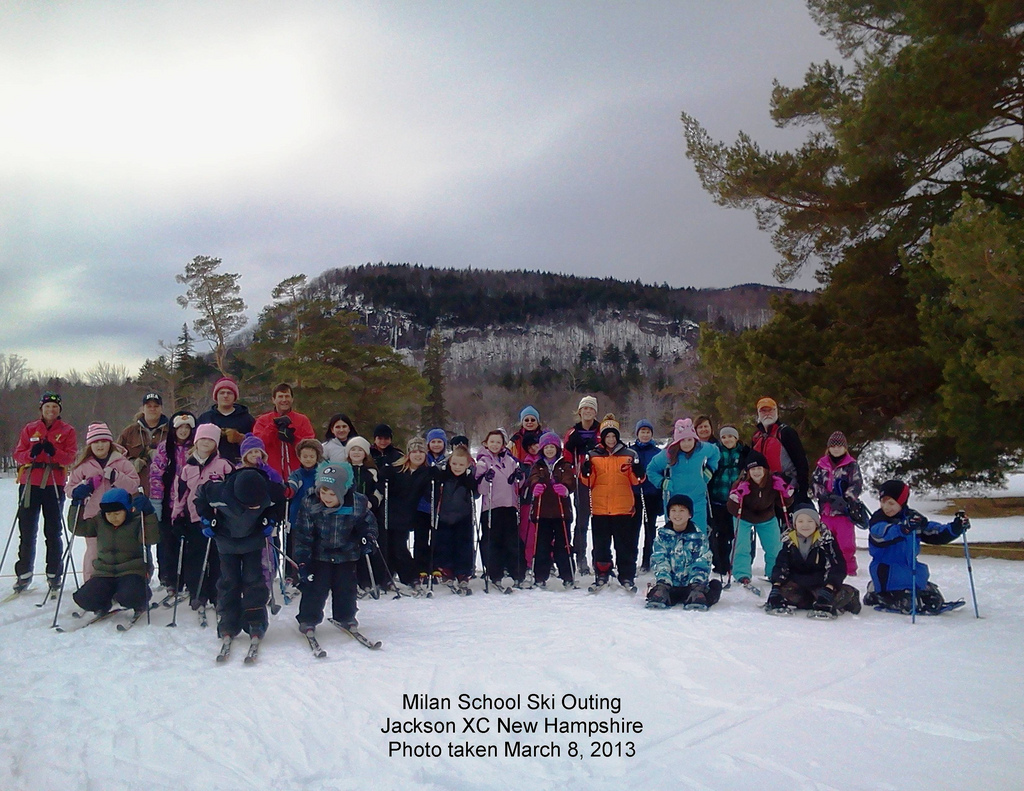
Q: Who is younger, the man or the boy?
A: The boy is younger than the man.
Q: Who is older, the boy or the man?
A: The man is older than the boy.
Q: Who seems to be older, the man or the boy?
A: The man is older than the boy.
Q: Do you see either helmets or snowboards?
A: No, there are no helmets or snowboards.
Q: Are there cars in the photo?
A: No, there are no cars.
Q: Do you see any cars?
A: No, there are no cars.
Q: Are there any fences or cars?
A: No, there are no cars or fences.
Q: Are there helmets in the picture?
A: No, there are no helmets.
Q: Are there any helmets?
A: No, there are no helmets.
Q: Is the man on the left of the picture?
A: Yes, the man is on the left of the image.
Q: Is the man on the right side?
A: No, the man is on the left of the image.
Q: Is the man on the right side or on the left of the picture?
A: The man is on the left of the image.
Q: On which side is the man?
A: The man is on the left of the image.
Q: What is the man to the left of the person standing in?
A: The man is standing in the snow.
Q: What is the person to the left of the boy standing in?
A: The man is standing in the snow.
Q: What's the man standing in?
A: The man is standing in the snow.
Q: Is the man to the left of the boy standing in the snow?
A: Yes, the man is standing in the snow.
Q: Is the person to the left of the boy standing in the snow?
A: Yes, the man is standing in the snow.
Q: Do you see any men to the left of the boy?
A: Yes, there is a man to the left of the boy.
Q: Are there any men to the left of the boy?
A: Yes, there is a man to the left of the boy.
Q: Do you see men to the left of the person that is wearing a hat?
A: Yes, there is a man to the left of the boy.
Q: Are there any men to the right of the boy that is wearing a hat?
A: No, the man is to the left of the boy.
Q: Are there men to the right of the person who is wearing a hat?
A: No, the man is to the left of the boy.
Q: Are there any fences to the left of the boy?
A: No, there is a man to the left of the boy.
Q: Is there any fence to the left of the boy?
A: No, there is a man to the left of the boy.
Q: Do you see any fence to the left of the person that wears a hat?
A: No, there is a man to the left of the boy.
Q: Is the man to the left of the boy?
A: Yes, the man is to the left of the boy.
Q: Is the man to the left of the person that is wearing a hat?
A: Yes, the man is to the left of the boy.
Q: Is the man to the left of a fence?
A: No, the man is to the left of the boy.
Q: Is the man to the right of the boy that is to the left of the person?
A: No, the man is to the left of the boy.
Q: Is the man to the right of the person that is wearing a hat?
A: No, the man is to the left of the boy.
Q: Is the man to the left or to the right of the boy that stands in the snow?
A: The man is to the left of the boy.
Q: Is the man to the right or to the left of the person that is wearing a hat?
A: The man is to the left of the boy.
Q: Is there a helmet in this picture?
A: No, there are no helmets.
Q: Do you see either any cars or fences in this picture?
A: No, there are no fences or cars.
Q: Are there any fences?
A: No, there are no fences.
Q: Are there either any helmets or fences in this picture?
A: No, there are no fences or helmets.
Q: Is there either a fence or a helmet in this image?
A: No, there are no fences or helmets.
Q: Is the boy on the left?
A: Yes, the boy is on the left of the image.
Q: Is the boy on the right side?
A: No, the boy is on the left of the image.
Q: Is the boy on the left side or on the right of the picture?
A: The boy is on the left of the image.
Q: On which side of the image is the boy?
A: The boy is on the left of the image.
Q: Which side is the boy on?
A: The boy is on the left of the image.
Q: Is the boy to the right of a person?
A: No, the boy is to the left of a person.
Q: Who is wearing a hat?
A: The boy is wearing a hat.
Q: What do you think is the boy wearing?
A: The boy is wearing a hat.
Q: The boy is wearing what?
A: The boy is wearing a hat.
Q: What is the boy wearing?
A: The boy is wearing a hat.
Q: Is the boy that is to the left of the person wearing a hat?
A: Yes, the boy is wearing a hat.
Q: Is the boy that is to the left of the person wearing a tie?
A: No, the boy is wearing a hat.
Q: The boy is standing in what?
A: The boy is standing in the snow.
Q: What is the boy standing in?
A: The boy is standing in the snow.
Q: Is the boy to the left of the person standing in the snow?
A: Yes, the boy is standing in the snow.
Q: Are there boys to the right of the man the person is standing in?
A: Yes, there is a boy to the right of the man.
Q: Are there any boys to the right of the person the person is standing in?
A: Yes, there is a boy to the right of the man.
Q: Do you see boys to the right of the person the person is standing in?
A: Yes, there is a boy to the right of the man.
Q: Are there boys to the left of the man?
A: No, the boy is to the right of the man.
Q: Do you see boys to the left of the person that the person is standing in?
A: No, the boy is to the right of the man.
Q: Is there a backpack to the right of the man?
A: No, there is a boy to the right of the man.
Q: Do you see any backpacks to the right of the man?
A: No, there is a boy to the right of the man.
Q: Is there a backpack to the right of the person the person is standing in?
A: No, there is a boy to the right of the man.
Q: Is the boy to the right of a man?
A: Yes, the boy is to the right of a man.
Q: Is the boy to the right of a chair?
A: No, the boy is to the right of a man.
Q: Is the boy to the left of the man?
A: No, the boy is to the right of the man.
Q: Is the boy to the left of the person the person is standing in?
A: No, the boy is to the right of the man.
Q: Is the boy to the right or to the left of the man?
A: The boy is to the right of the man.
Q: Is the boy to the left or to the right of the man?
A: The boy is to the right of the man.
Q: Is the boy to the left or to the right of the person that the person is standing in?
A: The boy is to the right of the man.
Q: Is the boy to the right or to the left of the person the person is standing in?
A: The boy is to the right of the man.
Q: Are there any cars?
A: No, there are no cars.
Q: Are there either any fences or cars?
A: No, there are no cars or fences.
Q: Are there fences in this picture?
A: No, there are no fences.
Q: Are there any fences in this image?
A: No, there are no fences.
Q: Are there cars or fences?
A: No, there are no fences or cars.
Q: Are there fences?
A: No, there are no fences.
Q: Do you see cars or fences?
A: No, there are no fences or cars.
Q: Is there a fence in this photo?
A: No, there are no fences.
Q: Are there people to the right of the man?
A: Yes, there is a person to the right of the man.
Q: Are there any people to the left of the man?
A: No, the person is to the right of the man.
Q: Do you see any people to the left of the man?
A: No, the person is to the right of the man.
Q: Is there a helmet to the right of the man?
A: No, there is a person to the right of the man.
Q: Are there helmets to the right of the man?
A: No, there is a person to the right of the man.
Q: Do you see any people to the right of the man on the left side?
A: Yes, there is a person to the right of the man.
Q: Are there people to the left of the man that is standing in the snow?
A: No, the person is to the right of the man.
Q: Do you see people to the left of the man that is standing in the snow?
A: No, the person is to the right of the man.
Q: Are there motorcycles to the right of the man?
A: No, there is a person to the right of the man.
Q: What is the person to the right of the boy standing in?
A: The person is standing in the snow.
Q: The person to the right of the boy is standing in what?
A: The person is standing in the snow.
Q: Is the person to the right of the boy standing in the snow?
A: Yes, the person is standing in the snow.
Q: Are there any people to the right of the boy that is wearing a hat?
A: Yes, there is a person to the right of the boy.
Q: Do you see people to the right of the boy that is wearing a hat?
A: Yes, there is a person to the right of the boy.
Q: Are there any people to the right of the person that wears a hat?
A: Yes, there is a person to the right of the boy.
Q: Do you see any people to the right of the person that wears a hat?
A: Yes, there is a person to the right of the boy.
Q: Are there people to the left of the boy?
A: No, the person is to the right of the boy.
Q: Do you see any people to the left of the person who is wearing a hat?
A: No, the person is to the right of the boy.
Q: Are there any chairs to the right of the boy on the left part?
A: No, there is a person to the right of the boy.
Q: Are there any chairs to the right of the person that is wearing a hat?
A: No, there is a person to the right of the boy.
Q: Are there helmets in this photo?
A: No, there are no helmets.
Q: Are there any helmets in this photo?
A: No, there are no helmets.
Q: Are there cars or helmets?
A: No, there are no helmets or cars.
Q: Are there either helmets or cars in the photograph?
A: No, there are no helmets or cars.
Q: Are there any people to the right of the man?
A: Yes, there is a person to the right of the man.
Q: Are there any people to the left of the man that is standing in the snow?
A: No, the person is to the right of the man.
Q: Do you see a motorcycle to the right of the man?
A: No, there is a person to the right of the man.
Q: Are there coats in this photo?
A: Yes, there is a coat.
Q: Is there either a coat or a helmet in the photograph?
A: Yes, there is a coat.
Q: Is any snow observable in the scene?
A: Yes, there is snow.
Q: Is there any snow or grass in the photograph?
A: Yes, there is snow.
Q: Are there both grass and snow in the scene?
A: No, there is snow but no grass.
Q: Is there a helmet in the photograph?
A: No, there are no helmets.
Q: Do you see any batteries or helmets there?
A: No, there are no helmets or batteries.